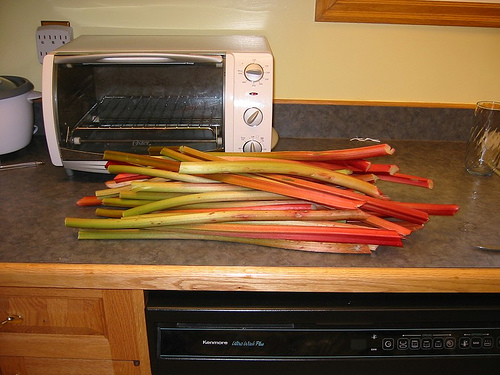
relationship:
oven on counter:
[39, 31, 282, 176] [1, 237, 496, 288]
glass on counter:
[461, 98, 499, 178] [2, 141, 499, 269]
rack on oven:
[80, 90, 215, 135] [39, 30, 283, 176]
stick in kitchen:
[58, 144, 460, 258] [19, 16, 487, 371]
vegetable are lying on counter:
[53, 141, 452, 255] [4, 136, 494, 285]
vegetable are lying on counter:
[160, 145, 427, 223] [4, 136, 494, 285]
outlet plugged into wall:
[33, 26, 75, 56] [271, 2, 495, 107]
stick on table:
[58, 144, 460, 258] [4, 138, 498, 272]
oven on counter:
[39, 30, 283, 176] [0, 87, 498, 269]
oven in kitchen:
[39, 31, 282, 176] [1, 125, 498, 307]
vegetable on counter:
[53, 141, 452, 255] [4, 136, 494, 285]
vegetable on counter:
[53, 141, 452, 255] [1, 86, 496, 298]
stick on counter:
[58, 144, 460, 258] [0, 123, 495, 283]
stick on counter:
[77, 226, 402, 240] [0, 123, 495, 283]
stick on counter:
[108, 172, 462, 213] [0, 123, 495, 283]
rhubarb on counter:
[64, 142, 462, 258] [3, 140, 499, 269]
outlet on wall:
[33, 26, 70, 68] [62, 3, 317, 42]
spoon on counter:
[472, 240, 498, 252] [2, 141, 499, 269]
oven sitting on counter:
[39, 31, 282, 176] [4, 136, 494, 285]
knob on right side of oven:
[242, 62, 265, 84] [39, 30, 283, 176]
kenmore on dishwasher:
[202, 337, 232, 350] [143, 291, 497, 373]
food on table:
[66, 130, 463, 258] [0, 106, 498, 267]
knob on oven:
[242, 62, 265, 84] [39, 30, 283, 176]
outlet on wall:
[33, 26, 75, 56] [2, 0, 498, 108]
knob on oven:
[234, 101, 269, 129] [39, 31, 282, 176]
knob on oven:
[230, 127, 272, 155] [39, 31, 282, 176]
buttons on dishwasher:
[371, 331, 496, 351] [143, 291, 497, 373]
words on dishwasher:
[195, 339, 270, 351] [153, 302, 499, 371]